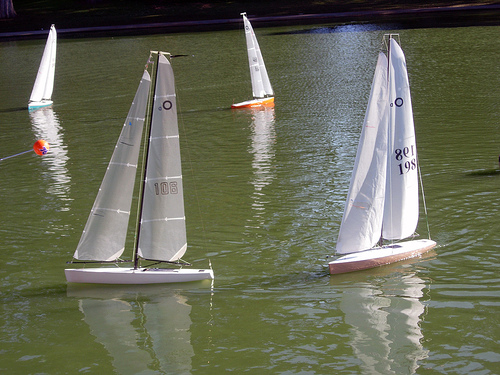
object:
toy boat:
[65, 50, 214, 284]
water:
[0, 6, 499, 374]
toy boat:
[328, 33, 436, 276]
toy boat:
[29, 23, 57, 113]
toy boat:
[232, 12, 277, 111]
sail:
[74, 51, 190, 269]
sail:
[238, 12, 274, 98]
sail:
[29, 24, 57, 103]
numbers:
[153, 181, 178, 195]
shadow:
[467, 168, 499, 176]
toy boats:
[28, 12, 437, 284]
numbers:
[395, 146, 416, 174]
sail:
[335, 38, 419, 255]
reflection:
[29, 104, 432, 374]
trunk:
[0, 1, 17, 20]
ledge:
[1, 0, 500, 41]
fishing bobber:
[33, 137, 49, 155]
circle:
[162, 99, 172, 110]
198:
[398, 158, 416, 175]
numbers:
[394, 146, 415, 161]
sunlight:
[0, 20, 500, 375]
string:
[1, 149, 33, 160]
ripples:
[1, 24, 498, 375]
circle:
[394, 97, 405, 108]